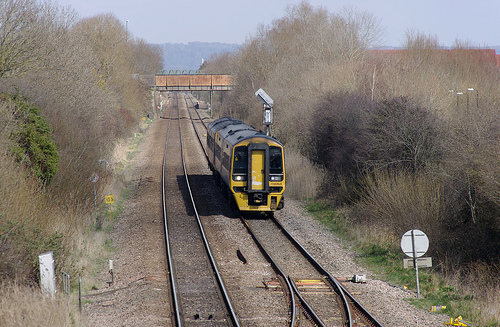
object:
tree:
[0, 85, 62, 191]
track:
[160, 92, 240, 327]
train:
[203, 116, 288, 220]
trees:
[0, 94, 61, 194]